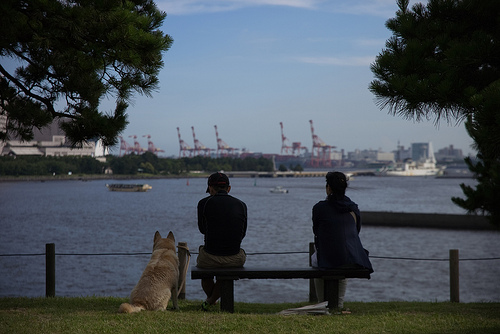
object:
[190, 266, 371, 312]
bench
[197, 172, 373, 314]
couple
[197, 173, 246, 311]
man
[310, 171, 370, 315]
people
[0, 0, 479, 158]
sky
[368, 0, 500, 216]
trees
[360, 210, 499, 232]
land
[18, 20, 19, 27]
leaves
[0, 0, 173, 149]
tree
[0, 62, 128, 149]
branch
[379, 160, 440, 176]
boat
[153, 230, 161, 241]
ears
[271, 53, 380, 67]
clouds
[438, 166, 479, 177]
boat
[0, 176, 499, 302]
water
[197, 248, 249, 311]
pants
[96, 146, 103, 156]
white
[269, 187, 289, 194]
boat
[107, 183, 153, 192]
boat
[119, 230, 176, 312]
dog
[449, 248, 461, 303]
pole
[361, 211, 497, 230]
boat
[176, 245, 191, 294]
leash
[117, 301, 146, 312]
tail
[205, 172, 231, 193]
cap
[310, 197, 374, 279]
jacket